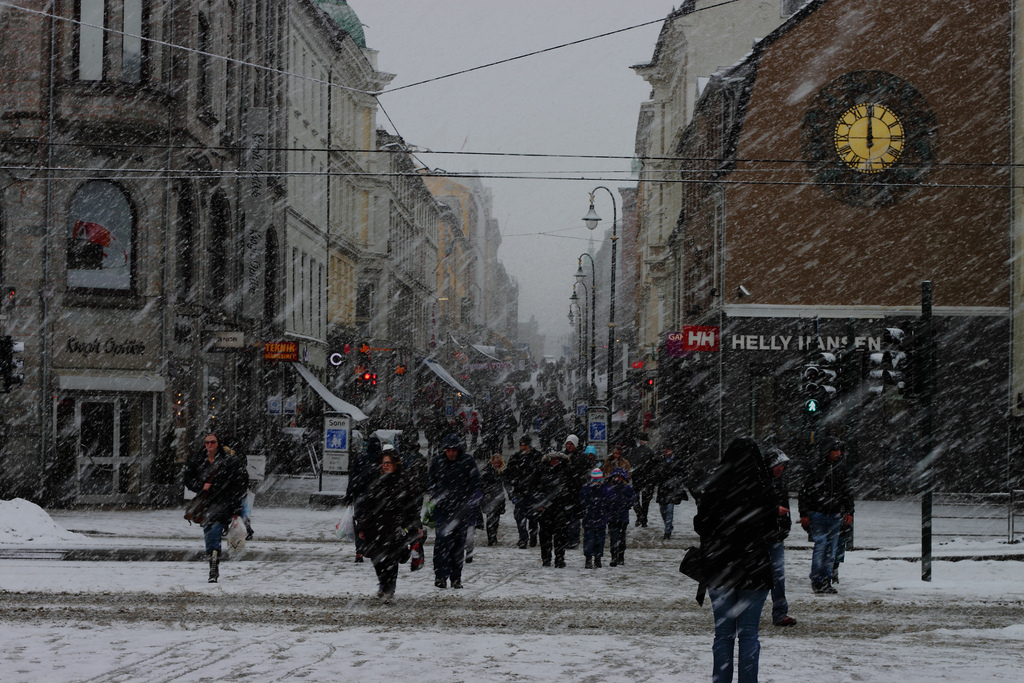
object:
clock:
[803, 69, 938, 212]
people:
[184, 433, 252, 582]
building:
[577, 0, 1024, 498]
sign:
[731, 333, 881, 354]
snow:
[0, 496, 1024, 683]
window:
[69, 178, 141, 296]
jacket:
[692, 438, 793, 610]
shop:
[663, 304, 1024, 503]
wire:
[0, 139, 1024, 192]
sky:
[350, 0, 686, 366]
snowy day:
[0, 0, 1024, 683]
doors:
[54, 366, 171, 509]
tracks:
[83, 628, 341, 683]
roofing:
[673, 2, 856, 141]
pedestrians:
[351, 450, 423, 606]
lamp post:
[581, 184, 617, 461]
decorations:
[65, 219, 128, 270]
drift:
[0, 495, 1010, 608]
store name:
[65, 336, 148, 355]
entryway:
[63, 394, 159, 504]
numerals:
[837, 105, 903, 173]